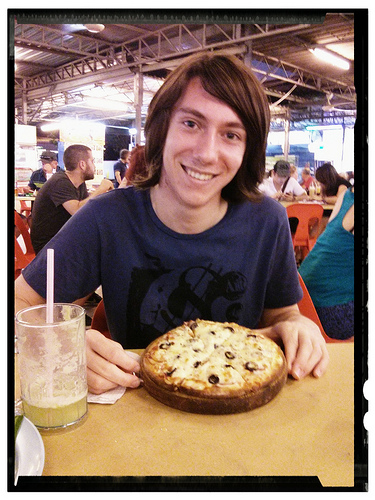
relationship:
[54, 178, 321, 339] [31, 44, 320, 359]
shirt on a man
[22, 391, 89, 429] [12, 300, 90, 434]
liquid inside glass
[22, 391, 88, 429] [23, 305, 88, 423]
liquid inside glass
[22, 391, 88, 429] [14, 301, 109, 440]
liquid inside glass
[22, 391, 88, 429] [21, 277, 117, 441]
liquid inside glass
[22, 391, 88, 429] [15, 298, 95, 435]
liquid inside glass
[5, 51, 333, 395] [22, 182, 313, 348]
man wearing shirt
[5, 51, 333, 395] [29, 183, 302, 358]
man wearing shirt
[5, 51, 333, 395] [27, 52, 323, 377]
man wearing shirt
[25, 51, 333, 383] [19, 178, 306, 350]
man wearing shirt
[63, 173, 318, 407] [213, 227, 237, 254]
body wearing shirt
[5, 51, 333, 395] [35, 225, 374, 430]
man seated at table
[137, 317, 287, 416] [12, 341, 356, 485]
pizza on table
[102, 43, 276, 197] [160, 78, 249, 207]
long hair on head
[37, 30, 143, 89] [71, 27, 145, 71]
railings on roof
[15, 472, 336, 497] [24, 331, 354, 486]
laptop on table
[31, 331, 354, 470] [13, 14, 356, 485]
table seen in photo